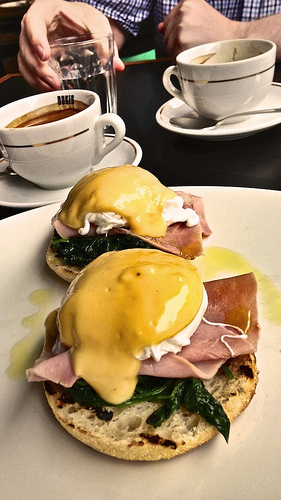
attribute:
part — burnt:
[142, 431, 178, 456]